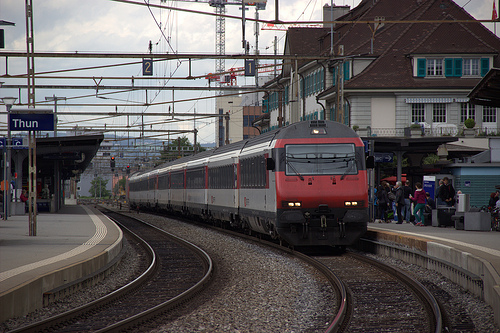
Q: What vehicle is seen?
A: Train.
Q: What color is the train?
A: Red and grey.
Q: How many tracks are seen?
A: 2.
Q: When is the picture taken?
A: Daytime.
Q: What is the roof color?
A: Brown.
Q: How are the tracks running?
A: Parallel to each other.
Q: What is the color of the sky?
A: Blue with some clouds.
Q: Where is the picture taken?
A: At a train station.